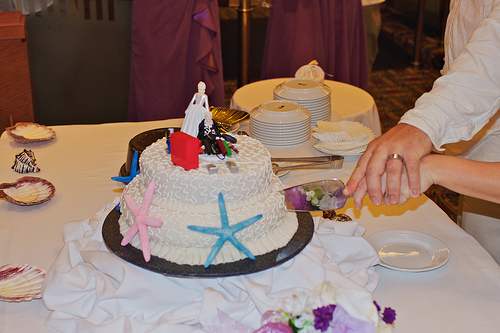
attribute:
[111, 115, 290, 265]
cake — wedding, blue, white, small, silver, cut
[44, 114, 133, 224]
table — sea, round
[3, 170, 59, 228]
shell — sea, white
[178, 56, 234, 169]
topper — wedding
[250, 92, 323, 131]
saucer — white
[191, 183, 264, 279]
starfish — blue, pink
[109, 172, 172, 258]
starfish — pink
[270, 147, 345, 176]
tong — silver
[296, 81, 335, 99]
plate — white, stack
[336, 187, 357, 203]
nail — finger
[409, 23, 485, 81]
shirt — white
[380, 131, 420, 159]
hand — male